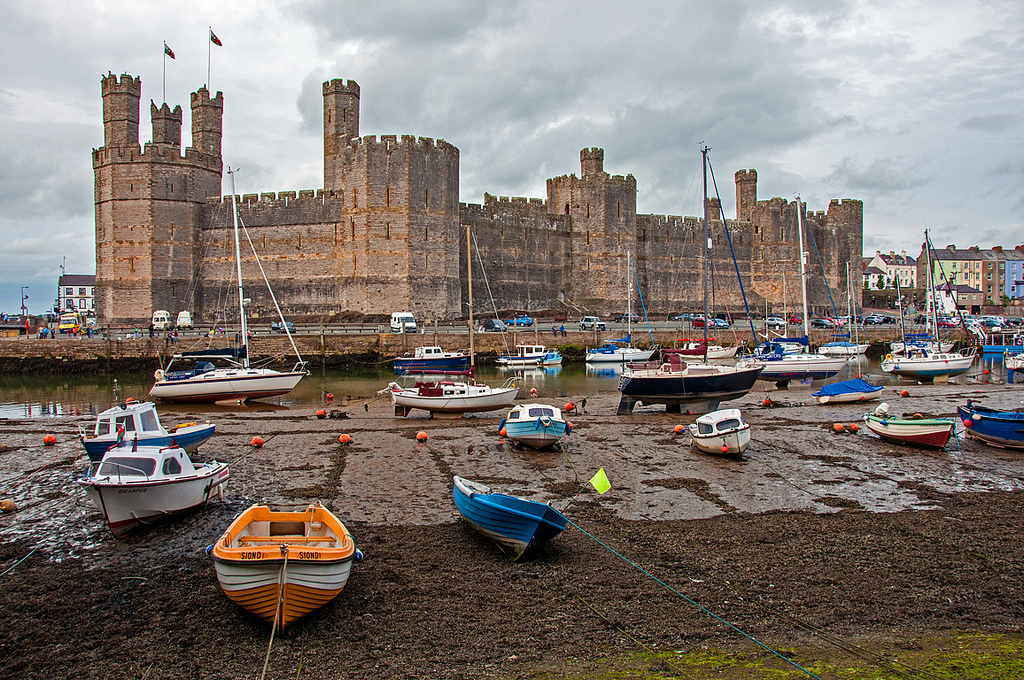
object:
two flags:
[162, 26, 220, 59]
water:
[0, 342, 1021, 427]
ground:
[0, 383, 1022, 680]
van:
[391, 312, 419, 334]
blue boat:
[454, 475, 567, 561]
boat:
[213, 502, 356, 635]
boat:
[687, 409, 752, 457]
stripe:
[688, 425, 751, 439]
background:
[0, 0, 1024, 326]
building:
[96, 70, 863, 323]